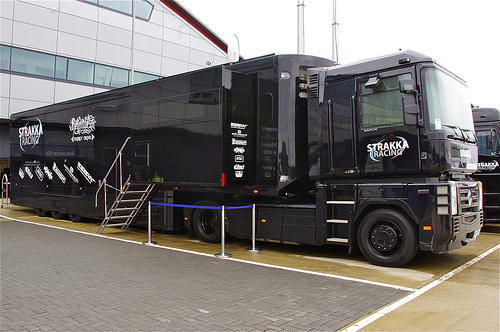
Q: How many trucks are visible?
A: 2.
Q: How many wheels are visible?
A: 5.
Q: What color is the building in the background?
A: White.